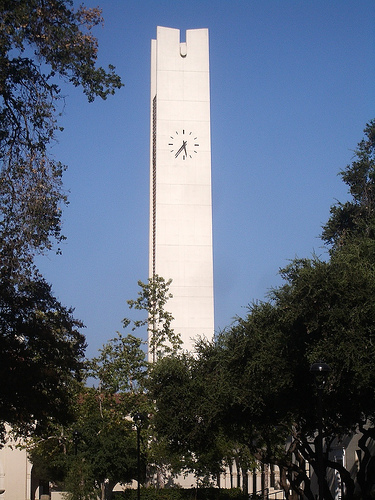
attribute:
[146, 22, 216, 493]
monument — tall, white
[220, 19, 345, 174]
sky — cloudless, blue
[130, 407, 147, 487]
light post — black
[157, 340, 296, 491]
trees — green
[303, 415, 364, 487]
building — white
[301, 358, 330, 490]
light post — tall, black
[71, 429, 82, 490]
light post — black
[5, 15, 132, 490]
leaves — green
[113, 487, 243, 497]
hedges — green, short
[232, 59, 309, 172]
sky — blue 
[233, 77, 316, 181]
sky — clear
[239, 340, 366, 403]
leaves — green 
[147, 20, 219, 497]
building — white 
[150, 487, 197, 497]
grass — green 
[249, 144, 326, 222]
sky — clear , blue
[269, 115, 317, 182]
sky — clear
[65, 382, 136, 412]
roof — brown 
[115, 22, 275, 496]
buildings — white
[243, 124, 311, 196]
sky — bright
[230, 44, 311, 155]
sky — rich blue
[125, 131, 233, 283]
tower — white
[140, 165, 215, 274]
tower — white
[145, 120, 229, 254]
tower — white